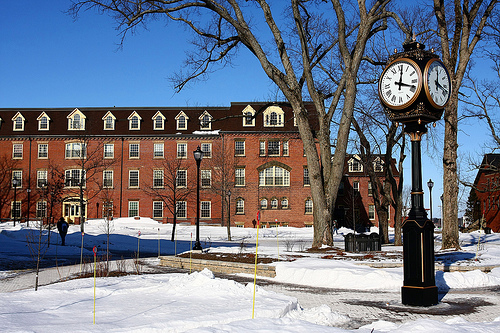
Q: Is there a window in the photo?
A: Yes, there is a window.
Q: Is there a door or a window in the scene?
A: Yes, there is a window.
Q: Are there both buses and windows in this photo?
A: No, there is a window but no buses.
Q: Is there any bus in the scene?
A: No, there are no buses.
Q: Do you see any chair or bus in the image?
A: No, there are no buses or chairs.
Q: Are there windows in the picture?
A: Yes, there is a window.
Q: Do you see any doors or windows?
A: Yes, there is a window.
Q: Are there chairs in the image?
A: No, there are no chairs.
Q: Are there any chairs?
A: No, there are no chairs.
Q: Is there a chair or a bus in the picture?
A: No, there are no chairs or buses.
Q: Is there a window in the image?
A: Yes, there is a window.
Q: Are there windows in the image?
A: Yes, there is a window.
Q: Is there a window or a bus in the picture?
A: Yes, there is a window.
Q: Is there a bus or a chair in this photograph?
A: No, there are no chairs or buses.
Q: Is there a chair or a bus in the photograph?
A: No, there are no chairs or buses.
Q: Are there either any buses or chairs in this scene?
A: No, there are no chairs or buses.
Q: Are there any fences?
A: No, there are no fences.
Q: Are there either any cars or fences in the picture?
A: No, there are no fences or cars.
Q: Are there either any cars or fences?
A: No, there are no fences or cars.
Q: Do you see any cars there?
A: No, there are no cars.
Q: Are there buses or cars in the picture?
A: No, there are no cars or buses.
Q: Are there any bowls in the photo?
A: No, there are no bowls.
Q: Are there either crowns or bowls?
A: No, there are no bowls or crowns.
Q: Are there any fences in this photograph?
A: No, there are no fences.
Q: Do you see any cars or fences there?
A: No, there are no fences or cars.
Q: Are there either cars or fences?
A: No, there are no fences or cars.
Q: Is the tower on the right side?
A: Yes, the tower is on the right of the image.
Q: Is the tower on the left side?
A: No, the tower is on the right of the image.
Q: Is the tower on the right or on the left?
A: The tower is on the right of the image.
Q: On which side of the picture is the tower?
A: The tower is on the right of the image.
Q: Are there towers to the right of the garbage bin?
A: Yes, there is a tower to the right of the garbage bin.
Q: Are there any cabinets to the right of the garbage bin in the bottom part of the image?
A: No, there is a tower to the right of the trash bin.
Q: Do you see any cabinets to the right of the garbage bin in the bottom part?
A: No, there is a tower to the right of the trash bin.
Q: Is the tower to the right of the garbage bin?
A: Yes, the tower is to the right of the garbage bin.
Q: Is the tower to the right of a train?
A: No, the tower is to the right of the garbage bin.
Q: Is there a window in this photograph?
A: Yes, there are windows.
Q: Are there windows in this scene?
A: Yes, there are windows.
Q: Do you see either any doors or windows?
A: Yes, there are windows.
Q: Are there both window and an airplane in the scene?
A: No, there are windows but no airplanes.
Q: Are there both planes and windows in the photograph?
A: No, there are windows but no airplanes.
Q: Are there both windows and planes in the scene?
A: No, there are windows but no airplanes.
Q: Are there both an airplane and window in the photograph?
A: No, there are windows but no airplanes.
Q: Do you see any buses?
A: No, there are no buses.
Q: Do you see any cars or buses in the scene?
A: No, there are no buses or cars.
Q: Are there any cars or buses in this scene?
A: No, there are no buses or cars.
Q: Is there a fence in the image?
A: No, there are no fences.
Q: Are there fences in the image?
A: No, there are no fences.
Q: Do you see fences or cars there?
A: No, there are no fences or cars.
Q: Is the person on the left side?
A: Yes, the person is on the left of the image.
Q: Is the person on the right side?
A: No, the person is on the left of the image.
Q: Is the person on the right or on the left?
A: The person is on the left of the image.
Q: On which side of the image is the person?
A: The person is on the left of the image.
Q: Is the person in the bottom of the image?
A: Yes, the person is in the bottom of the image.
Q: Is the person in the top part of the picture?
A: No, the person is in the bottom of the image.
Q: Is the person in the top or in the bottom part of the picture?
A: The person is in the bottom of the image.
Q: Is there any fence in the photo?
A: No, there are no fences.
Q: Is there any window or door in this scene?
A: Yes, there is a window.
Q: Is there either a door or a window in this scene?
A: Yes, there is a window.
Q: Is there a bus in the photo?
A: No, there are no buses.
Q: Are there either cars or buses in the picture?
A: No, there are no buses or cars.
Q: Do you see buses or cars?
A: No, there are no buses or cars.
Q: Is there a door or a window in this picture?
A: Yes, there is a window.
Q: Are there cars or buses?
A: No, there are no cars or buses.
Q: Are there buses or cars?
A: No, there are no cars or buses.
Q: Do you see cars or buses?
A: No, there are no cars or buses.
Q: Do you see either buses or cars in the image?
A: No, there are no cars or buses.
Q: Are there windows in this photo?
A: Yes, there is a window.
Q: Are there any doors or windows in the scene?
A: Yes, there is a window.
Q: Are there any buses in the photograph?
A: No, there are no buses.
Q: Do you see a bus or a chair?
A: No, there are no buses or chairs.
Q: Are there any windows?
A: Yes, there is a window.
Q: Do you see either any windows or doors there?
A: Yes, there is a window.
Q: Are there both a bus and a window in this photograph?
A: No, there is a window but no buses.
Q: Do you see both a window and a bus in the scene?
A: No, there is a window but no buses.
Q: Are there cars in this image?
A: No, there are no cars.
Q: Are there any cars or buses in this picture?
A: No, there are no cars or buses.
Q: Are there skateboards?
A: No, there are no skateboards.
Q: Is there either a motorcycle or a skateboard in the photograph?
A: No, there are no skateboards or motorcycles.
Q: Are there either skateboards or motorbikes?
A: No, there are no skateboards or motorbikes.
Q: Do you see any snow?
A: Yes, there is snow.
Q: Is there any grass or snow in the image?
A: Yes, there is snow.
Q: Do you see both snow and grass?
A: No, there is snow but no grass.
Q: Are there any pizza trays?
A: No, there are no pizza trays.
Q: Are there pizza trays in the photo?
A: No, there are no pizza trays.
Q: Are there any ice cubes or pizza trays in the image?
A: No, there are no pizza trays or ice cubes.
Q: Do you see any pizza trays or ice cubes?
A: No, there are no pizza trays or ice cubes.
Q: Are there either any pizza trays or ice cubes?
A: No, there are no pizza trays or ice cubes.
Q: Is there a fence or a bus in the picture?
A: No, there are no fences or buses.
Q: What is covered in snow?
A: The sidewalk is covered in snow.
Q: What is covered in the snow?
A: The sidewalk is covered in snow.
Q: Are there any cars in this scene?
A: No, there are no cars.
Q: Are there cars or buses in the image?
A: No, there are no cars or buses.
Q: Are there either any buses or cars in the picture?
A: No, there are no cars or buses.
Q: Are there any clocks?
A: Yes, there is a clock.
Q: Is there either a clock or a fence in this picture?
A: Yes, there is a clock.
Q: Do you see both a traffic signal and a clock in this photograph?
A: No, there is a clock but no traffic lights.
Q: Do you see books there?
A: No, there are no books.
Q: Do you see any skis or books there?
A: No, there are no books or skis.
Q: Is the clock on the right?
A: Yes, the clock is on the right of the image.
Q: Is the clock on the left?
A: No, the clock is on the right of the image.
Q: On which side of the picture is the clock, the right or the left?
A: The clock is on the right of the image.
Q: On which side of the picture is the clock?
A: The clock is on the right of the image.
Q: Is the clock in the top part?
A: Yes, the clock is in the top of the image.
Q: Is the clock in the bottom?
A: No, the clock is in the top of the image.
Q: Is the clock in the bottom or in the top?
A: The clock is in the top of the image.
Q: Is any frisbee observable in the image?
A: No, there are no frisbees.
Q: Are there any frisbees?
A: No, there are no frisbees.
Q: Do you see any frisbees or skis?
A: No, there are no frisbees or skis.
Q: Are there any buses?
A: No, there are no buses.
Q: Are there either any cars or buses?
A: No, there are no buses or cars.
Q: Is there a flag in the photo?
A: No, there are no flags.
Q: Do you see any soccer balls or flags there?
A: No, there are no flags or soccer balls.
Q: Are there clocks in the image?
A: Yes, there is a clock.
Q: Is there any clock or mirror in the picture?
A: Yes, there is a clock.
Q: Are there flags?
A: No, there are no flags.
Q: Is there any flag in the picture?
A: No, there are no flags.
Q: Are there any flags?
A: No, there are no flags.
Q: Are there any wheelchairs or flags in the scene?
A: No, there are no flags or wheelchairs.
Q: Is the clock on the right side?
A: Yes, the clock is on the right of the image.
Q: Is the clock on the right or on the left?
A: The clock is on the right of the image.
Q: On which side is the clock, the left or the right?
A: The clock is on the right of the image.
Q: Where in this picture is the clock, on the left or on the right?
A: The clock is on the right of the image.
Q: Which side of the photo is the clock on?
A: The clock is on the right of the image.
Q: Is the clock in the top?
A: Yes, the clock is in the top of the image.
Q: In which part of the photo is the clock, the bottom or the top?
A: The clock is in the top of the image.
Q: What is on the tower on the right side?
A: The clock is on the tower.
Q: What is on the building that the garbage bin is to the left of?
A: The clock is on the tower.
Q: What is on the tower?
A: The clock is on the tower.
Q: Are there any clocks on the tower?
A: Yes, there is a clock on the tower.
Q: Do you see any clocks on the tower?
A: Yes, there is a clock on the tower.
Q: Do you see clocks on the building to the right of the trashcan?
A: Yes, there is a clock on the tower.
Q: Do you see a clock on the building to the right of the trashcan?
A: Yes, there is a clock on the tower.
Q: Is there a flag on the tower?
A: No, there is a clock on the tower.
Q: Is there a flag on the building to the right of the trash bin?
A: No, there is a clock on the tower.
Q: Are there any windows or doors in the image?
A: Yes, there is a window.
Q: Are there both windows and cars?
A: No, there is a window but no cars.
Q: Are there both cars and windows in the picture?
A: No, there is a window but no cars.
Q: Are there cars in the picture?
A: No, there are no cars.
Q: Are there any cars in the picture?
A: No, there are no cars.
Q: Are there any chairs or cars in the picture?
A: No, there are no cars or chairs.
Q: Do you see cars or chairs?
A: No, there are no cars or chairs.